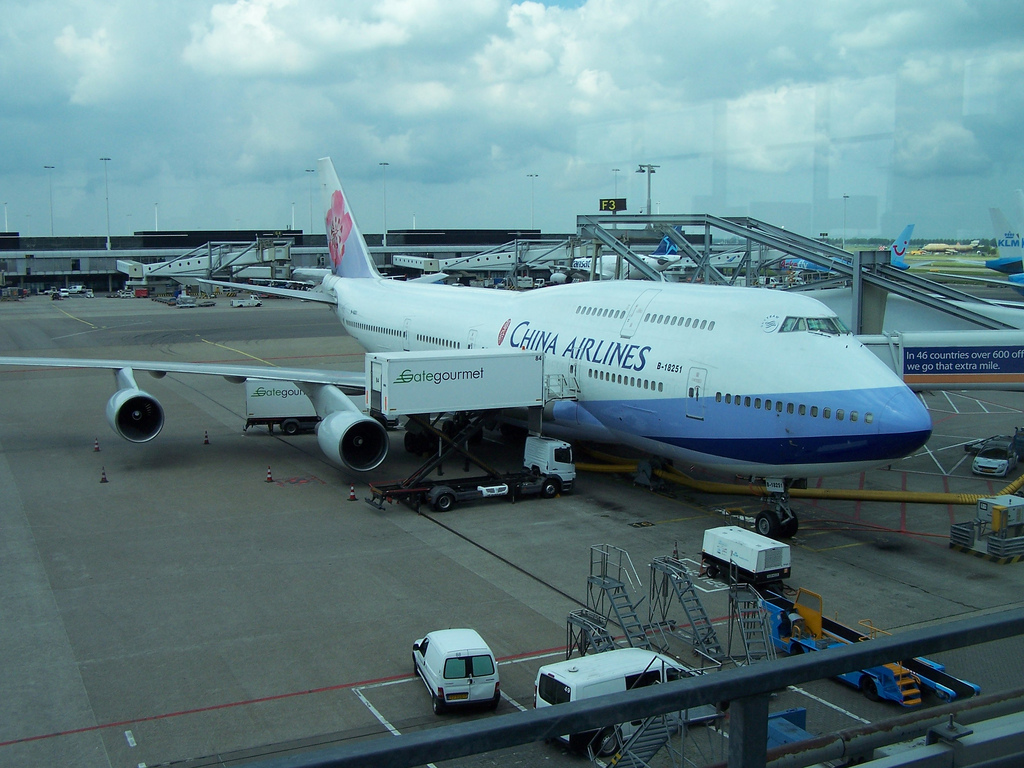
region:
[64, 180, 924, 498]
white plane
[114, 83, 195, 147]
white clouds in blue sky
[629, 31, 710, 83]
white clouds in blue sky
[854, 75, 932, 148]
white clouds in blue sky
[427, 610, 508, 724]
white truck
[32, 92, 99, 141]
white clouds in blue sky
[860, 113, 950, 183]
white clouds in blue sky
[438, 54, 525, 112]
white clouds in blue sky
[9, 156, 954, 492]
white and blue plane in airport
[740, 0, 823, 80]
white snow in blue sky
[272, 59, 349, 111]
white snow in blue sky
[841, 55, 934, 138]
white snow in blue sky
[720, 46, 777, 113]
white snow in blue sky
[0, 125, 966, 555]
Plane on the ground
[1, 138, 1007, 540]
Plane is on the ground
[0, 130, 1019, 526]
Airplane on the ground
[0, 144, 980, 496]
Airplane is on the ground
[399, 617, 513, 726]
Van is parked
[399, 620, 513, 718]
White van is parked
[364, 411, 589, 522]
Truck is parked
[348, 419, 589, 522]
Truck is parked next to plane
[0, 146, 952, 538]
Blue and white plane on the ground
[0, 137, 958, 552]
Blue and white airplane is on the ground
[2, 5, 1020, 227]
clouds in the sky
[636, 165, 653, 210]
a lamp post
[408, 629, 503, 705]
a white van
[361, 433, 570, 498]
a large white truck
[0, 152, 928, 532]
a large white airplane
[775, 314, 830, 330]
the windshield on the plane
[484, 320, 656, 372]
writing on the airplane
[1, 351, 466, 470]
the wing on the airplane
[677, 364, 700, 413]
the door on the airplane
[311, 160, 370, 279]
the tail wing on the airplane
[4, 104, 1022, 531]
airplane parked at airport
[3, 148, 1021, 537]
parked airplane is white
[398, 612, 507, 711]
small van at airport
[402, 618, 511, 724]
small van is white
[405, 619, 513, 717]
white van is small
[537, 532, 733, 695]
set of rolling stairs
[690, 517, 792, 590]
luggage cart under airplane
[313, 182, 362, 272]
logo on tail of plane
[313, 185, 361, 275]
logo on tail is pink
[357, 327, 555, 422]
white cart against airplane